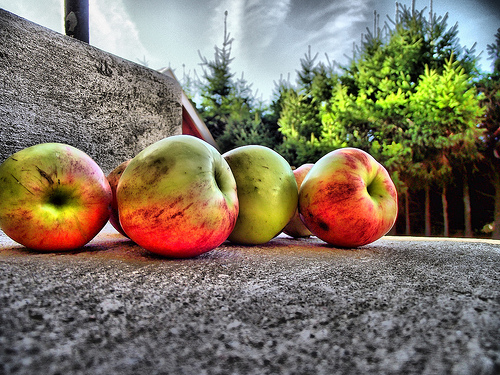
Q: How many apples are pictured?
A: Six.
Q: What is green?
A: Trees.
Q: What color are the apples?
A: Red and green.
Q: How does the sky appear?
A: Cloudy.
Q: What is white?
A: Clouds.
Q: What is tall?
A: The trees.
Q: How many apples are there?
A: Six.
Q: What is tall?
A: Trees.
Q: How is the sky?
A: Cloudy.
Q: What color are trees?
A: Green.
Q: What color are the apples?
A: Red and green.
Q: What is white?
A: Clouds.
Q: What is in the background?
A: Trees.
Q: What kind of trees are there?
A: Evergreen.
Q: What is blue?
A: Sky.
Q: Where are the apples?
A: On stone surface.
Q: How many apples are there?
A: 6.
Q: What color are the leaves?
A: Green.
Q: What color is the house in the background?
A: Red.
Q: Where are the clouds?
A: In the sky.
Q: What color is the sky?
A: Blue.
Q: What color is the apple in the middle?
A: Green.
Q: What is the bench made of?
A: Wood.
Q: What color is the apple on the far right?
A: Red and green.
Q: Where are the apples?
A: On the bench.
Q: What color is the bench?
A: Gray.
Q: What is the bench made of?
A: Wood.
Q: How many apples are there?
A: 6.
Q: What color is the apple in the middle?
A: Green.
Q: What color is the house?
A: Red.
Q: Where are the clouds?
A: In the sky.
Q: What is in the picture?
A: Apples.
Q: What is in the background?
A: Trees.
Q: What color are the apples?
A: Red and green.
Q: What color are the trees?
A: Green.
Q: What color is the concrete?
A: Grey.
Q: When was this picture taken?
A: Daytime.